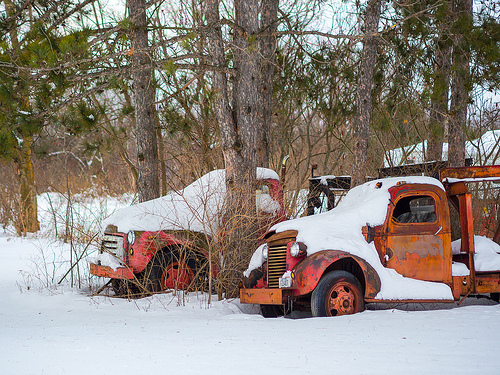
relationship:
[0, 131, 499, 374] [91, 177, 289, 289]
snow on hood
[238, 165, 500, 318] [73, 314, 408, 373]
old truck sitting in sun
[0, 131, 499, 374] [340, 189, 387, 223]
snow on windshield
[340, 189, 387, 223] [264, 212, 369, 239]
windshield and hood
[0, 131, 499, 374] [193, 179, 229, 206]
snow on windshield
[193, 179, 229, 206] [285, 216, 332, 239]
windshield and hood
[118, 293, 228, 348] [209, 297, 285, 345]
ground covered in snow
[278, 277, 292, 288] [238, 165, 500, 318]
plate on front of old truck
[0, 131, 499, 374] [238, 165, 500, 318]
snow covering a old truck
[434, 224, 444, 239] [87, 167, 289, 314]
handle on a truck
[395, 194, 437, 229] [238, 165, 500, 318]
window on old truck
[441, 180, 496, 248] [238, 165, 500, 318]
rack on back of old truck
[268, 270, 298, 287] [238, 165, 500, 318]
plate on old truck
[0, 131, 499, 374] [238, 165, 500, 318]
snow on old truck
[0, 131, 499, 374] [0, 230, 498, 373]
snow on ground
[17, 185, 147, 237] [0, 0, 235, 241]
snow on tree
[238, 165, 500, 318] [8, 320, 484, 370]
old truck covered in snow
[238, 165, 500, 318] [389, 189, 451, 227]
old truck has window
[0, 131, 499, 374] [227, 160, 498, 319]
snow covering truck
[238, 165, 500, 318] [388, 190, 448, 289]
old truck has door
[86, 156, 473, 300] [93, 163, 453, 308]
truck are covered in snow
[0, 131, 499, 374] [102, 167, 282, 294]
snow covering truck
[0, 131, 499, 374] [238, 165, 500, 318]
snow covering old truck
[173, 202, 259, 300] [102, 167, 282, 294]
branches are in front of truck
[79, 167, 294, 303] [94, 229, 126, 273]
truck has grill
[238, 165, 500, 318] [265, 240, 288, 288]
old truck has rusty grill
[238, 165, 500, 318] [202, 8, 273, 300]
old truck standing between tree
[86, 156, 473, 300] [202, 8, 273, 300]
truck standing between tree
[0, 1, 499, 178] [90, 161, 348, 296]
trees standing between truck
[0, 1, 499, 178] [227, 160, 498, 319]
trees standing between truck